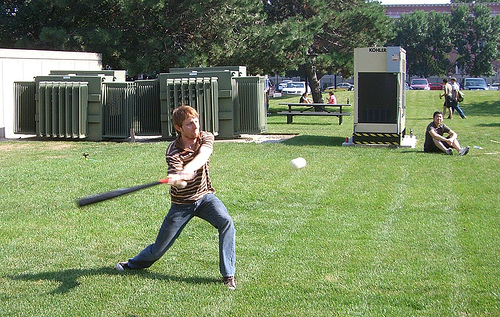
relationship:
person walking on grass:
[438, 77, 455, 118] [1, 82, 498, 314]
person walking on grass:
[448, 77, 468, 121] [1, 82, 498, 314]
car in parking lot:
[401, 67, 497, 89] [286, 49, 498, 89]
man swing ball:
[66, 91, 268, 293] [286, 148, 308, 172]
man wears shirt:
[116, 105, 238, 291] [164, 126, 222, 195]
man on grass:
[418, 106, 470, 167] [384, 135, 487, 175]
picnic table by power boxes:
[275, 102, 350, 123] [14, 45, 407, 148]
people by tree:
[301, 90, 341, 107] [257, 6, 347, 71]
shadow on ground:
[6, 265, 221, 295] [1, 84, 497, 313]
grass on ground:
[1, 82, 498, 314] [1, 84, 497, 313]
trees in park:
[2, 10, 488, 105] [15, 75, 495, 315]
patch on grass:
[250, 223, 290, 255] [1, 82, 498, 314]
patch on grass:
[388, 192, 406, 226] [356, 155, 436, 276]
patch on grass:
[293, 254, 323, 277] [1, 82, 498, 314]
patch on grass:
[46, 226, 66, 246] [1, 82, 498, 314]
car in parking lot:
[276, 77, 310, 97] [267, 65, 498, 107]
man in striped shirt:
[116, 105, 238, 291] [165, 130, 217, 203]